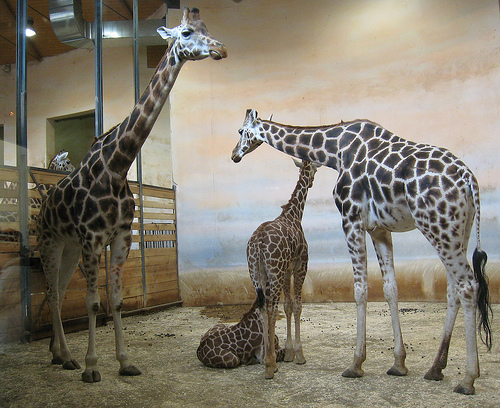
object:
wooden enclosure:
[1, 166, 180, 343]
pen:
[361, 0, 481, 296]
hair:
[472, 248, 497, 353]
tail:
[462, 190, 497, 281]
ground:
[421, 152, 452, 192]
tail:
[469, 172, 494, 352]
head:
[156, 6, 228, 61]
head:
[47, 149, 75, 172]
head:
[290, 157, 317, 188]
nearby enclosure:
[1, 165, 182, 345]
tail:
[250, 242, 280, 300]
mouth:
[231, 152, 242, 163]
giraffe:
[196, 286, 290, 368]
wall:
[319, 15, 465, 110]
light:
[102, 25, 123, 39]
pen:
[168, 0, 348, 303]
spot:
[393, 150, 418, 184]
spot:
[333, 129, 360, 151]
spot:
[310, 129, 326, 149]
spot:
[78, 195, 100, 223]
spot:
[99, 135, 116, 168]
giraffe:
[48, 149, 75, 172]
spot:
[125, 109, 147, 135]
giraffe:
[35, 7, 227, 383]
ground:
[357, 104, 436, 158]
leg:
[418, 217, 498, 399]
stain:
[191, 295, 298, 334]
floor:
[54, 362, 493, 408]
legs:
[109, 236, 141, 376]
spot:
[61, 186, 81, 198]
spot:
[99, 197, 116, 223]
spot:
[107, 145, 130, 182]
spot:
[122, 130, 136, 155]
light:
[26, 28, 38, 37]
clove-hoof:
[82, 370, 102, 383]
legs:
[292, 265, 308, 364]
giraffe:
[247, 157, 323, 379]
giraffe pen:
[0, 0, 499, 407]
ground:
[1, 299, 497, 403]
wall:
[0, 0, 500, 306]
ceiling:
[0, 1, 180, 77]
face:
[231, 129, 248, 160]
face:
[178, 20, 228, 56]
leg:
[342, 228, 368, 379]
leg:
[367, 230, 409, 376]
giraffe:
[230, 108, 492, 396]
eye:
[239, 130, 244, 135]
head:
[231, 109, 263, 163]